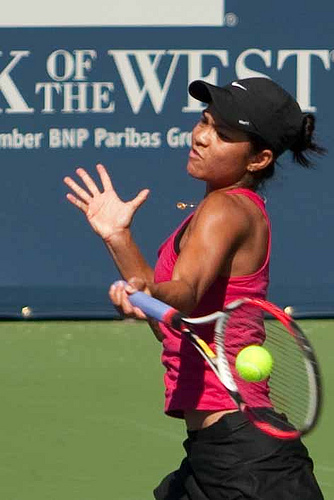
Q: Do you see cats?
A: No, there are no cats.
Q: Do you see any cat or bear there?
A: No, there are no cats or bears.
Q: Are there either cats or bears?
A: No, there are no cats or bears.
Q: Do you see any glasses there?
A: No, there are no glasses.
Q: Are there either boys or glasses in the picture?
A: No, there are no glasses or boys.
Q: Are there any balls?
A: Yes, there is a ball.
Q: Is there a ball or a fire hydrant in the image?
A: Yes, there is a ball.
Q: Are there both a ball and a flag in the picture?
A: No, there is a ball but no flags.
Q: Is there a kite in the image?
A: No, there are no kites.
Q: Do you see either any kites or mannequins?
A: No, there are no kites or mannequins.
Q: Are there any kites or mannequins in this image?
A: No, there are no kites or mannequins.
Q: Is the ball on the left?
A: No, the ball is on the right of the image.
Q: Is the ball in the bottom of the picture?
A: Yes, the ball is in the bottom of the image.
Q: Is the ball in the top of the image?
A: No, the ball is in the bottom of the image.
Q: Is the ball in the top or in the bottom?
A: The ball is in the bottom of the image.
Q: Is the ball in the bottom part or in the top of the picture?
A: The ball is in the bottom of the image.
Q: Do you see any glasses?
A: No, there are no glasses.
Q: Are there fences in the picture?
A: No, there are no fences.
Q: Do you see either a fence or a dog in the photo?
A: No, there are no fences or dogs.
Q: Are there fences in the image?
A: No, there are no fences.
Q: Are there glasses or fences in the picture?
A: No, there are no fences or glasses.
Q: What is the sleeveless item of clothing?
A: The clothing item is a shirt.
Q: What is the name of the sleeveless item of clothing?
A: The clothing item is a shirt.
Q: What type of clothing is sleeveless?
A: The clothing is a shirt.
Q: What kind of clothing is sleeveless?
A: The clothing is a shirt.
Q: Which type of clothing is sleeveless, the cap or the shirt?
A: The shirt is sleeveless.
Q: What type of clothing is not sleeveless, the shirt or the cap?
A: The cap is not sleeveless.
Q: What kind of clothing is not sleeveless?
A: The clothing is a cap.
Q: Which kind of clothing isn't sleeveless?
A: The clothing is a cap.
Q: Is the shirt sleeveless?
A: Yes, the shirt is sleeveless.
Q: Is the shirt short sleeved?
A: No, the shirt is sleeveless.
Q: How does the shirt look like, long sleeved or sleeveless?
A: The shirt is sleeveless.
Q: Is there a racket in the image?
A: Yes, there is a racket.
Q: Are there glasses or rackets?
A: Yes, there is a racket.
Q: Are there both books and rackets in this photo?
A: No, there is a racket but no books.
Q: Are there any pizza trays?
A: No, there are no pizza trays.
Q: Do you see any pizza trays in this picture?
A: No, there are no pizza trays.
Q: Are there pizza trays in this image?
A: No, there are no pizza trays.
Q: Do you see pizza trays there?
A: No, there are no pizza trays.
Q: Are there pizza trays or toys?
A: No, there are no pizza trays or toys.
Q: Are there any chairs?
A: No, there are no chairs.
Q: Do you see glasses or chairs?
A: No, there are no chairs or glasses.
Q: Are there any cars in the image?
A: No, there are no cars.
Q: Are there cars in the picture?
A: No, there are no cars.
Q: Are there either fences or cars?
A: No, there are no cars or fences.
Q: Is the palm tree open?
A: Yes, the palm tree is open.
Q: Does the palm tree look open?
A: Yes, the palm tree is open.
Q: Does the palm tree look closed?
A: No, the palm tree is open.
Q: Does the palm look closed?
A: No, the palm is open.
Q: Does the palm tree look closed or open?
A: The palm tree is open.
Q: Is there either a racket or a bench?
A: Yes, there is a racket.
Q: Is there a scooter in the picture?
A: No, there are no scooters.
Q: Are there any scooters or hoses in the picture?
A: No, there are no scooters or hoses.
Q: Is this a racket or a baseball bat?
A: This is a racket.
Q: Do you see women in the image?
A: Yes, there is a woman.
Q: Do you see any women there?
A: Yes, there is a woman.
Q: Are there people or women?
A: Yes, there is a woman.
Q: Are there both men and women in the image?
A: No, there is a woman but no men.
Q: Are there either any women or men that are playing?
A: Yes, the woman is playing.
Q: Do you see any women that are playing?
A: Yes, there is a woman that is playing.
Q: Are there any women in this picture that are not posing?
A: Yes, there is a woman that is playing.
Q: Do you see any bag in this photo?
A: No, there are no bags.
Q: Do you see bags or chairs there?
A: No, there are no bags or chairs.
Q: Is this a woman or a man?
A: This is a woman.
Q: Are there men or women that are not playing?
A: No, there is a woman but she is playing.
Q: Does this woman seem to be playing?
A: Yes, the woman is playing.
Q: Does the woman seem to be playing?
A: Yes, the woman is playing.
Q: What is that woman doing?
A: The woman is playing.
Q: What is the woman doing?
A: The woman is playing.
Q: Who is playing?
A: The woman is playing.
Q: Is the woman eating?
A: No, the woman is playing.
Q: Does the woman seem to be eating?
A: No, the woman is playing.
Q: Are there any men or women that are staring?
A: No, there is a woman but she is playing.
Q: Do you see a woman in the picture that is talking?
A: No, there is a woman but she is playing.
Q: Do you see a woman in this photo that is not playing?
A: No, there is a woman but she is playing.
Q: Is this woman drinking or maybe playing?
A: The woman is playing.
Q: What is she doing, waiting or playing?
A: The woman is playing.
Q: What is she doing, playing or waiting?
A: The woman is playing.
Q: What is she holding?
A: The woman is holding the racket.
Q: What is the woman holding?
A: The woman is holding the racket.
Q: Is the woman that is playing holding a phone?
A: No, the woman is holding the racket.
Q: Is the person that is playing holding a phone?
A: No, the woman is holding the racket.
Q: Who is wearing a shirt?
A: The woman is wearing a shirt.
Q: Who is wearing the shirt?
A: The woman is wearing a shirt.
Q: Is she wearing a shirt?
A: Yes, the woman is wearing a shirt.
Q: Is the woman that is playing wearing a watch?
A: No, the woman is wearing a shirt.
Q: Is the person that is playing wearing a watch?
A: No, the woman is wearing a shirt.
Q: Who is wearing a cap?
A: The woman is wearing a cap.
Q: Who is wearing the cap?
A: The woman is wearing a cap.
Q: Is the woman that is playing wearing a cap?
A: Yes, the woman is wearing a cap.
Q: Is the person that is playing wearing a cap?
A: Yes, the woman is wearing a cap.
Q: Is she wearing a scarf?
A: No, the woman is wearing a cap.